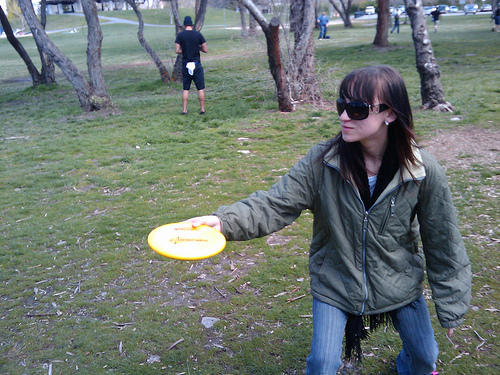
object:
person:
[430, 6, 445, 33]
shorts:
[182, 61, 206, 90]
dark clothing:
[174, 31, 206, 62]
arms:
[174, 15, 208, 113]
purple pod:
[145, 221, 227, 261]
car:
[464, 3, 478, 15]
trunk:
[0, 0, 114, 111]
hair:
[311, 65, 428, 203]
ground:
[0, 6, 499, 375]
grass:
[0, 113, 315, 374]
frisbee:
[147, 222, 228, 261]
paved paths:
[2, 14, 166, 46]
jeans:
[307, 302, 439, 375]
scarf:
[341, 145, 406, 368]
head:
[335, 65, 400, 142]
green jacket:
[211, 141, 470, 327]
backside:
[172, 16, 210, 115]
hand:
[184, 216, 220, 234]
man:
[317, 11, 330, 40]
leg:
[310, 302, 348, 374]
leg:
[389, 301, 447, 374]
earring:
[384, 120, 388, 126]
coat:
[212, 137, 471, 328]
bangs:
[339, 67, 379, 106]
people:
[181, 65, 474, 374]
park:
[0, 0, 500, 374]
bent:
[156, 101, 174, 117]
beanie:
[183, 16, 194, 27]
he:
[174, 15, 209, 114]